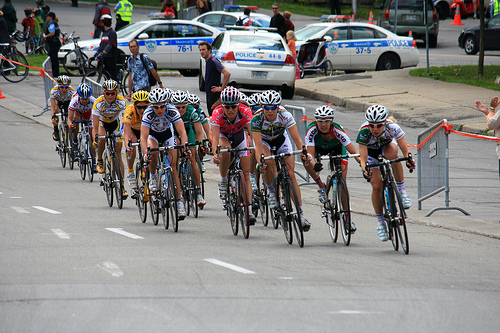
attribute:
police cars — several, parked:
[50, 2, 422, 96]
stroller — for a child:
[298, 33, 336, 78]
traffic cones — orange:
[364, 10, 467, 43]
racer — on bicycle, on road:
[305, 102, 371, 246]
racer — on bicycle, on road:
[136, 90, 197, 232]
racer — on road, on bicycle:
[356, 100, 420, 259]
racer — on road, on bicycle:
[250, 88, 313, 246]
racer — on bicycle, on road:
[133, 87, 192, 237]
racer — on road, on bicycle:
[244, 89, 314, 251]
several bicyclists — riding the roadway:
[43, 74, 423, 264]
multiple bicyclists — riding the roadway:
[46, 71, 430, 263]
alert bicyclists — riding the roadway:
[46, 71, 427, 267]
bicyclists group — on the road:
[45, 72, 423, 261]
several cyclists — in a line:
[39, 71, 418, 261]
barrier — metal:
[409, 113, 471, 222]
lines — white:
[25, 201, 265, 284]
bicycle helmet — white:
[362, 98, 394, 135]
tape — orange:
[413, 117, 466, 152]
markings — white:
[32, 203, 255, 279]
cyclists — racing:
[31, 61, 423, 247]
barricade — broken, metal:
[380, 115, 473, 225]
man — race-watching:
[189, 35, 230, 110]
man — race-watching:
[121, 39, 159, 91]